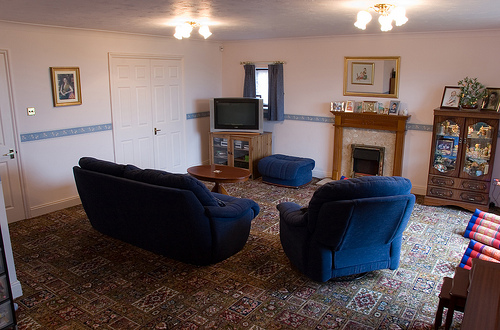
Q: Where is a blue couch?
A: In a living room.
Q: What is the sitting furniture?
A: A sofa and recliner.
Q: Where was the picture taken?
A: In a living room.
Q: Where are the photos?
A: On the fireplace mantel.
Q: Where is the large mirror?
A: Over the fireplace.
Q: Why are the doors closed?
A: For privacy.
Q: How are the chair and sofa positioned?
A: Facing the fireplace and TV.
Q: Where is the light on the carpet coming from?
A: Another window or door.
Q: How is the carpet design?
A: Square and diamond patterns.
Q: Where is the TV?
A: In the corner.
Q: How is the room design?
A: White with blue trim.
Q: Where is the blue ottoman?
A: By the TV.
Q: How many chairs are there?
A: Two.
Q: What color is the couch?
A: Blue.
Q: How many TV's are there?
A: One.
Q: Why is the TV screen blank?
A: It's off.